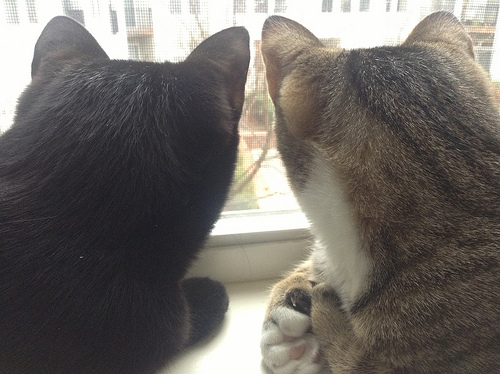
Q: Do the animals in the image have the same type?
A: Yes, all the animals are cats.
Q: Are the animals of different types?
A: No, all the animals are cats.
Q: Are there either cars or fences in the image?
A: No, there are no fences or cars.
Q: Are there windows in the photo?
A: Yes, there is a window.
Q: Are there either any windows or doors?
A: Yes, there is a window.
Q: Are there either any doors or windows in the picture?
A: Yes, there is a window.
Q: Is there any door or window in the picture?
A: Yes, there is a window.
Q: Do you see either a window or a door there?
A: Yes, there is a window.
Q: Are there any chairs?
A: Yes, there is a chair.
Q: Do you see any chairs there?
A: Yes, there is a chair.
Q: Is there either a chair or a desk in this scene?
A: Yes, there is a chair.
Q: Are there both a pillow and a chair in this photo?
A: No, there is a chair but no pillows.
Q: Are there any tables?
A: No, there are no tables.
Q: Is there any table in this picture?
A: No, there are no tables.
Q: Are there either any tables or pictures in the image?
A: No, there are no tables or pictures.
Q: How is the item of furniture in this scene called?
A: The piece of furniture is a chair.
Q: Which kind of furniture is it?
A: The piece of furniture is a chair.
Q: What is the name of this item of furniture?
A: This is a chair.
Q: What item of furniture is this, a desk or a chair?
A: This is a chair.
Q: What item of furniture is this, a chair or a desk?
A: This is a chair.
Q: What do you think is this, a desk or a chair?
A: This is a chair.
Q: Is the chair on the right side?
A: Yes, the chair is on the right of the image.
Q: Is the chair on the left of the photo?
A: No, the chair is on the right of the image.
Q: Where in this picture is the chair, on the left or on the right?
A: The chair is on the right of the image.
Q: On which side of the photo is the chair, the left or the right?
A: The chair is on the right of the image.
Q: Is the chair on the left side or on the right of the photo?
A: The chair is on the right of the image.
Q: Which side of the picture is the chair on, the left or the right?
A: The chair is on the right of the image.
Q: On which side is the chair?
A: The chair is on the right of the image.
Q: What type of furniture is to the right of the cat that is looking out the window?
A: The piece of furniture is a chair.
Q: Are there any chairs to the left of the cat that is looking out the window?
A: No, the chair is to the right of the cat.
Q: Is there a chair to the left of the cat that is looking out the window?
A: No, the chair is to the right of the cat.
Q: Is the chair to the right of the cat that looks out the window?
A: Yes, the chair is to the right of the cat.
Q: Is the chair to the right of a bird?
A: No, the chair is to the right of the cat.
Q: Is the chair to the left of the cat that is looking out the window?
A: No, the chair is to the right of the cat.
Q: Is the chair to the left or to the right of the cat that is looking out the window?
A: The chair is to the right of the cat.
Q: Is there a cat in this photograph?
A: Yes, there is a cat.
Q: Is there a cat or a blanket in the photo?
A: Yes, there is a cat.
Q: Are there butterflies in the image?
A: No, there are no butterflies.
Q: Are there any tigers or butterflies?
A: No, there are no butterflies or tigers.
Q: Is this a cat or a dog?
A: This is a cat.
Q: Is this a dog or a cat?
A: This is a cat.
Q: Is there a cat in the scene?
A: Yes, there is a cat.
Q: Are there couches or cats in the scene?
A: Yes, there is a cat.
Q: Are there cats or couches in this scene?
A: Yes, there is a cat.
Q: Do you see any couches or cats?
A: Yes, there is a cat.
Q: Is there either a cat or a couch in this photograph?
A: Yes, there is a cat.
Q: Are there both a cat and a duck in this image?
A: No, there is a cat but no ducks.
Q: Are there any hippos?
A: No, there are no hippos.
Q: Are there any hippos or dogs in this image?
A: No, there are no hippos or dogs.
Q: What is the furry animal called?
A: The animal is a cat.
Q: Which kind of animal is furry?
A: The animal is a cat.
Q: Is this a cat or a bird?
A: This is a cat.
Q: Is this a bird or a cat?
A: This is a cat.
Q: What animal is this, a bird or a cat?
A: This is a cat.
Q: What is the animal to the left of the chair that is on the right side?
A: The animal is a cat.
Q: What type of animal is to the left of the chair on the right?
A: The animal is a cat.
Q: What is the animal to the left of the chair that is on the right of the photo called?
A: The animal is a cat.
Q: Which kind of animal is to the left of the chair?
A: The animal is a cat.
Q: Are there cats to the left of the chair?
A: Yes, there is a cat to the left of the chair.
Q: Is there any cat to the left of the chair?
A: Yes, there is a cat to the left of the chair.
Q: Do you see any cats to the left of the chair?
A: Yes, there is a cat to the left of the chair.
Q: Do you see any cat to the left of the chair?
A: Yes, there is a cat to the left of the chair.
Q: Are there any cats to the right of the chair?
A: No, the cat is to the left of the chair.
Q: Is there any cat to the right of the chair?
A: No, the cat is to the left of the chair.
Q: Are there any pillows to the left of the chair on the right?
A: No, there is a cat to the left of the chair.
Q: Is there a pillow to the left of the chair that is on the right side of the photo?
A: No, there is a cat to the left of the chair.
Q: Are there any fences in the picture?
A: No, there are no fences.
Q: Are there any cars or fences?
A: No, there are no fences or cars.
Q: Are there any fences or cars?
A: No, there are no fences or cars.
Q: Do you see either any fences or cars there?
A: No, there are no fences or cars.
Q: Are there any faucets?
A: No, there are no faucets.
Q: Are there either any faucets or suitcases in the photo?
A: No, there are no faucets or suitcases.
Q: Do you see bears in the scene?
A: No, there are no bears.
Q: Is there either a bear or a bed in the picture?
A: No, there are no bears or beds.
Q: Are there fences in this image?
A: No, there are no fences.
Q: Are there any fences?
A: No, there are no fences.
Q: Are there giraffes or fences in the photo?
A: No, there are no fences or giraffes.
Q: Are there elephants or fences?
A: No, there are no fences or elephants.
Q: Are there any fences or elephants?
A: No, there are no fences or elephants.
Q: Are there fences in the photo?
A: No, there are no fences.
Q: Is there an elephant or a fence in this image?
A: No, there are no fences or elephants.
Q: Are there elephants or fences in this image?
A: No, there are no fences or elephants.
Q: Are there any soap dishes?
A: No, there are no soap dishes.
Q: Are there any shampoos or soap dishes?
A: No, there are no soap dishes or shampoos.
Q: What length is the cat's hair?
A: The hair is long.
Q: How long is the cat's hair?
A: The hair is long.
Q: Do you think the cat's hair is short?
A: No, the hair is long.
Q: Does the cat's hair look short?
A: No, the hair is long.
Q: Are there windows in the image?
A: Yes, there are windows.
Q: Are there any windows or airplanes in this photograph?
A: Yes, there are windows.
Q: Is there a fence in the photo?
A: No, there are no fences.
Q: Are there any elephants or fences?
A: No, there are no fences or elephants.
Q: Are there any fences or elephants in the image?
A: No, there are no fences or elephants.